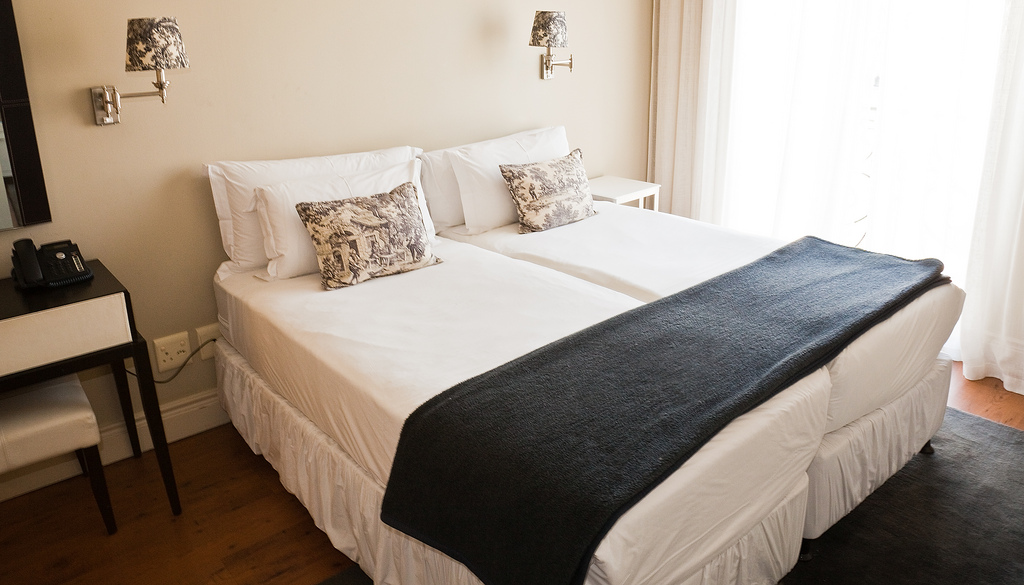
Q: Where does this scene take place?
A: In a hotel room.